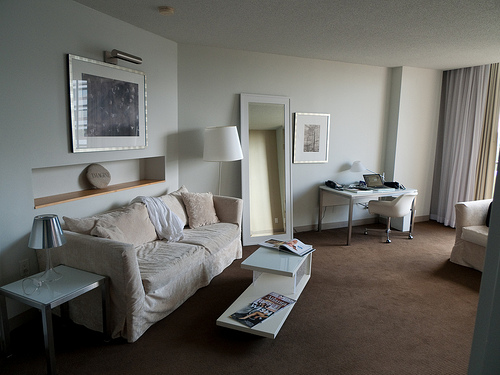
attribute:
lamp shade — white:
[352, 158, 367, 176]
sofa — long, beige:
[35, 190, 245, 345]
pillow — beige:
[186, 190, 220, 230]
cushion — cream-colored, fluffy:
[462, 224, 488, 249]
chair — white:
[360, 188, 422, 245]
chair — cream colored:
[359, 184, 419, 247]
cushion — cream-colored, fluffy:
[63, 202, 158, 243]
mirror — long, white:
[246, 101, 288, 241]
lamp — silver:
[203, 125, 242, 197]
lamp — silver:
[350, 161, 362, 183]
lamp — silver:
[26, 215, 67, 275]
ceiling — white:
[85, 4, 496, 71]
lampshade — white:
[196, 122, 232, 159]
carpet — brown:
[326, 236, 440, 363]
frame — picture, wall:
[286, 107, 331, 172]